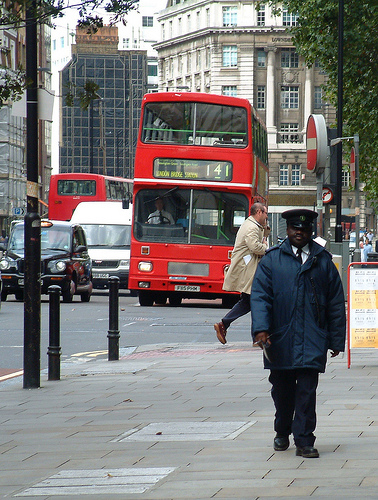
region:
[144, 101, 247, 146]
windshield on the bus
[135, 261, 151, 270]
headlight on the bus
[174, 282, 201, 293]
license plate on bus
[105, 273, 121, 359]
pole on the sidewalk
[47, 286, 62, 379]
pole on the sidewalk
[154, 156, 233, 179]
bus number on bus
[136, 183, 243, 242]
windshield on bottom deck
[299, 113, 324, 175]
stop sign on pole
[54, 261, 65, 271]
headlight on bus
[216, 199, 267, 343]
man crossing street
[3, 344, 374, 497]
the stone sidewalk for people to walk on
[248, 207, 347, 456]
a man in uniform walking down the sidewalk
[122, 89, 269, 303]
a double decker bus driving down the road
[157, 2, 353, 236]
a tall building with many windows on the side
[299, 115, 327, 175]
the sign attached to the pole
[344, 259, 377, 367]
an advertisement sitting on the sidewalk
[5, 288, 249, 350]
the road the cars are driving on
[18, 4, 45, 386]
the tall pole on next to the street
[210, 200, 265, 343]
the man walking on the sidewalk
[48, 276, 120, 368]
the metal poles next to the curb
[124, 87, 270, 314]
A red double decker bus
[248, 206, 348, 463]
A man in a police officers outfit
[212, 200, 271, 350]
A man walking in a tan coat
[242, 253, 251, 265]
A white paper sticking out of a man's pocket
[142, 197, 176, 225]
The driver of the double decker bus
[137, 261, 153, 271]
The headlight of the double decker bus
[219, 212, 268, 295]
A tan coat being worn by a man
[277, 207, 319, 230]
a black police officer's hat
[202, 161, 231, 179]
The route number in neon green on the bus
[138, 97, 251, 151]
The top window of the bus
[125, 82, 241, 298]
a red double decker bus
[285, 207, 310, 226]
a black hat on a head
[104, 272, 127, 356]
a black metal pole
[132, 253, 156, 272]
an oblong headlight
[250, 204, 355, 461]
a policeman wearing a blue coat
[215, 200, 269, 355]
a man talking on a phone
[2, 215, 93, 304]
a black Bentley driving on the street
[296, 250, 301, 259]
a black neck tie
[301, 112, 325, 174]
a red and white sign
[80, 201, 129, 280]
a white van behind the Bentley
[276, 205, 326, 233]
black conductor's hat on man's head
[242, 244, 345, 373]
man wearing blue coat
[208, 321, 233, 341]
brown shoes on man's foot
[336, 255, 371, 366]
white sign with red edges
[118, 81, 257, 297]
double decker bus on the street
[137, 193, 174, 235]
man in driver's seat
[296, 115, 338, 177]
red and white round sign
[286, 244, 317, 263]
black tie around man's neck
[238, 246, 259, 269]
white paper in man's jacket pocket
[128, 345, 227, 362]
pink tiles on the side walk